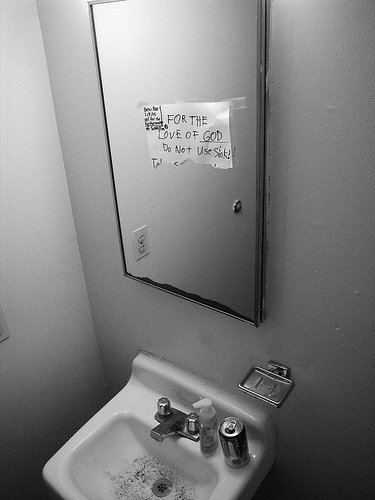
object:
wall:
[0, 0, 111, 500]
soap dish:
[235, 359, 296, 408]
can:
[216, 416, 252, 469]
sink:
[40, 350, 279, 499]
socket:
[131, 224, 152, 262]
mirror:
[82, 2, 270, 329]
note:
[143, 100, 233, 172]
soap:
[192, 396, 219, 457]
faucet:
[149, 397, 201, 444]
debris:
[114, 479, 134, 499]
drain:
[151, 476, 172, 499]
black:
[139, 456, 150, 478]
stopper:
[232, 200, 244, 215]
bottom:
[149, 473, 176, 500]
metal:
[255, 378, 274, 392]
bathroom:
[0, 0, 375, 500]